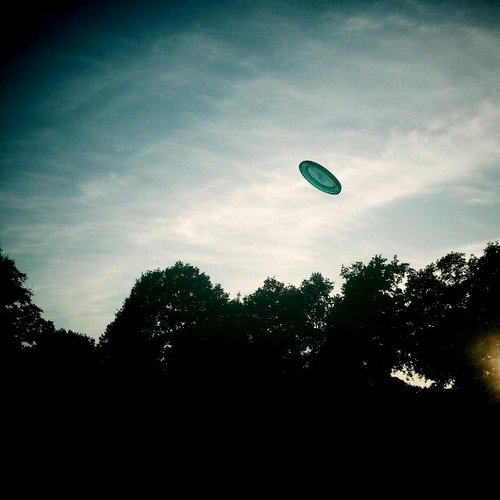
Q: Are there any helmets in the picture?
A: No, there are no helmets.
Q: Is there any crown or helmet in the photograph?
A: No, there are no helmets or crowns.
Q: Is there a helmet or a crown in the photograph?
A: No, there are no helmets or crowns.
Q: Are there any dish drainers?
A: No, there are no dish drainers.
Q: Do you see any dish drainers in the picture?
A: No, there are no dish drainers.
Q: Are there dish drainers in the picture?
A: No, there are no dish drainers.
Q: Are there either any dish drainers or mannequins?
A: No, there are no dish drainers or mannequins.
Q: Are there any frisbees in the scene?
A: Yes, there is a frisbee.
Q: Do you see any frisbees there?
A: Yes, there is a frisbee.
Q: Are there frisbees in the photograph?
A: Yes, there is a frisbee.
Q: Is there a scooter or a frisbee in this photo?
A: Yes, there is a frisbee.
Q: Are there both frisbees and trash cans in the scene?
A: No, there is a frisbee but no trash cans.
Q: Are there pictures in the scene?
A: No, there are no pictures.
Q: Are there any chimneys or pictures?
A: No, there are no pictures or chimneys.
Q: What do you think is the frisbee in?
A: The frisbee is in the air.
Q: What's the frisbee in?
A: The frisbee is in the air.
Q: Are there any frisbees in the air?
A: Yes, there is a frisbee in the air.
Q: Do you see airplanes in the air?
A: No, there is a frisbee in the air.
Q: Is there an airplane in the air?
A: No, there is a frisbee in the air.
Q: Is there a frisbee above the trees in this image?
A: Yes, there is a frisbee above the trees.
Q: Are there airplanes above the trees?
A: No, there is a frisbee above the trees.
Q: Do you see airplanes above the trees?
A: No, there is a frisbee above the trees.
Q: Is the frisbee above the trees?
A: Yes, the frisbee is above the trees.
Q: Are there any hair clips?
A: No, there are no hair clips.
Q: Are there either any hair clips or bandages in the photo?
A: No, there are no hair clips or bandages.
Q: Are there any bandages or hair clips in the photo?
A: No, there are no hair clips or bandages.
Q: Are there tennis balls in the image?
A: No, there are no tennis balls.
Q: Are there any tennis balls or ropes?
A: No, there are no tennis balls or ropes.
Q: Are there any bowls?
A: No, there are no bowls.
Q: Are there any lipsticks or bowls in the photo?
A: No, there are no bowls or lipsticks.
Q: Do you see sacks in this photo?
A: No, there are no sacks.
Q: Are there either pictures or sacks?
A: No, there are no sacks or pictures.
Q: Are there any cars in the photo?
A: No, there are no cars.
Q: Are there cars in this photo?
A: No, there are no cars.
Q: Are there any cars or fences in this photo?
A: No, there are no cars or fences.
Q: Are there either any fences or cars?
A: No, there are no cars or fences.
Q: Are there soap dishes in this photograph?
A: No, there are no soap dishes.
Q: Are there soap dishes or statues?
A: No, there are no soap dishes or statues.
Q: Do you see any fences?
A: No, there are no fences.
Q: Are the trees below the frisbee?
A: Yes, the trees are below the frisbee.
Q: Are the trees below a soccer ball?
A: No, the trees are below the frisbee.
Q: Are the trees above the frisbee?
A: Yes, the trees are above the frisbee.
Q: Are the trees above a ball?
A: No, the trees are above the frisbee.